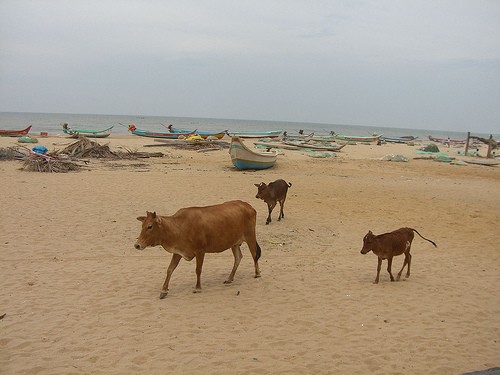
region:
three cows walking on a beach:
[127, 167, 462, 355]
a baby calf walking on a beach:
[356, 228, 436, 287]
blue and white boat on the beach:
[212, 137, 286, 172]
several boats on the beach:
[1, 118, 480, 180]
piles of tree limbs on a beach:
[2, 138, 162, 187]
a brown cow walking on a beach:
[121, 198, 261, 303]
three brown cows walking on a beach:
[121, 163, 441, 304]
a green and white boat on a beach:
[53, 122, 119, 140]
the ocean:
[28, 110, 413, 143]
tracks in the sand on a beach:
[75, 318, 405, 373]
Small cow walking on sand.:
[352, 230, 435, 338]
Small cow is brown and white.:
[359, 214, 442, 339]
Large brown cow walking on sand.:
[128, 200, 260, 325]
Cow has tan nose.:
[131, 243, 158, 268]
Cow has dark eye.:
[138, 220, 153, 235]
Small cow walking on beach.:
[252, 170, 302, 229]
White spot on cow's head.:
[253, 170, 276, 218]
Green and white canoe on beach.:
[20, 113, 123, 146]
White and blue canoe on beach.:
[236, 130, 275, 209]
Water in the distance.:
[136, 108, 279, 140]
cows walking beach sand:
[67, 168, 449, 319]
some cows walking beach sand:
[118, 166, 448, 331]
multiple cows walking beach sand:
[112, 165, 437, 330]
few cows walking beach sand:
[105, 155, 455, 320]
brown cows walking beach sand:
[106, 152, 451, 332]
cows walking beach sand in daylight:
[87, 162, 457, 342]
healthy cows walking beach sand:
[95, 167, 455, 337]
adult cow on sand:
[120, 186, 265, 313]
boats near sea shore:
[16, 85, 476, 180]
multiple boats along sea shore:
[21, 102, 468, 177]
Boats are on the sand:
[2, 112, 482, 174]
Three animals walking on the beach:
[105, 160, 450, 317]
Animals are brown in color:
[111, 156, 446, 307]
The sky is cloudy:
[3, 1, 498, 116]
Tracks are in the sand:
[45, 302, 452, 367]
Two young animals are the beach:
[246, 165, 441, 295]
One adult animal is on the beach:
[115, 190, 262, 315]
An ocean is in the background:
[0, 107, 497, 144]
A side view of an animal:
[129, 188, 269, 310]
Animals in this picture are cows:
[131, 163, 445, 313]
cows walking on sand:
[127, 176, 438, 332]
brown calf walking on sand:
[342, 197, 452, 289]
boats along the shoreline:
[132, 101, 347, 188]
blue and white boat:
[207, 129, 290, 170]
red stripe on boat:
[228, 139, 287, 178]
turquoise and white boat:
[57, 116, 136, 141]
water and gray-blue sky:
[165, 61, 284, 131]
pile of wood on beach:
[68, 136, 179, 166]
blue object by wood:
[26, 139, 56, 172]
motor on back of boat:
[45, 116, 128, 150]